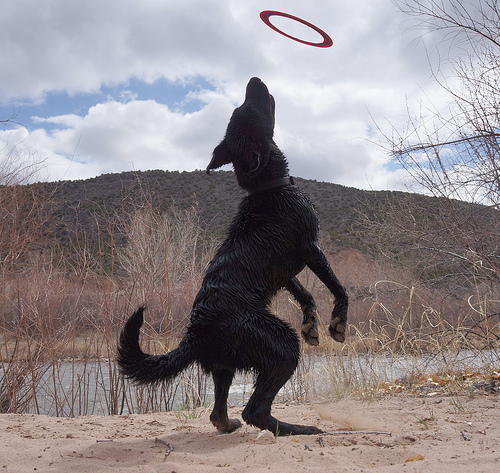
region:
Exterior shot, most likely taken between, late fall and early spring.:
[5, 1, 495, 462]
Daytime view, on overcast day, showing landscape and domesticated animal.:
[5, 5, 496, 470]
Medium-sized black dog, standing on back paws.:
[125, 60, 355, 450]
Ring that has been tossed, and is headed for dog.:
[256, 5, 329, 65]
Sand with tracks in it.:
[81, 417, 481, 469]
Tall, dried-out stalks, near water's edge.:
[12, 260, 497, 415]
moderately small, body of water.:
[28, 345, 493, 412]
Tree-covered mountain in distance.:
[15, 172, 493, 287]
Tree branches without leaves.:
[387, 7, 497, 232]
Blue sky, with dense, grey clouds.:
[13, 20, 485, 193]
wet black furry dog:
[110, 73, 350, 438]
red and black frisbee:
[256, 8, 337, 53]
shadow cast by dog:
[59, 428, 258, 465]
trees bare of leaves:
[1, 142, 207, 413]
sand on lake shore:
[7, 391, 493, 470]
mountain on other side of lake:
[3, 168, 498, 286]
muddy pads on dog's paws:
[298, 315, 345, 348]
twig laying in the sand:
[152, 433, 174, 462]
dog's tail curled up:
[115, 300, 198, 385]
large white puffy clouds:
[7, 4, 490, 194]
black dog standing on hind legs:
[175, 71, 340, 438]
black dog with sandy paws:
[291, 314, 353, 350]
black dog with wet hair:
[193, 130, 277, 375]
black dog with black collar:
[245, 167, 314, 199]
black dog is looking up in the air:
[211, 8, 333, 178]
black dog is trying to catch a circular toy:
[194, 3, 343, 243]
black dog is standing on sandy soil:
[69, 405, 414, 452]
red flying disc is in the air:
[243, 9, 350, 64]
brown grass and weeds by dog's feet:
[288, 326, 473, 400]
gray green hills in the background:
[21, 164, 490, 284]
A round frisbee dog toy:
[257, 8, 332, 49]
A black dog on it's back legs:
[116, 74, 349, 434]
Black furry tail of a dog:
[114, 306, 197, 381]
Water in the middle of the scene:
[0, 345, 497, 411]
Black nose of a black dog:
[244, 74, 262, 87]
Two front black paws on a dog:
[279, 243, 349, 345]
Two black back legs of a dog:
[197, 313, 320, 436]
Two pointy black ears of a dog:
[202, 139, 261, 174]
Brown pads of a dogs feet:
[300, 316, 345, 344]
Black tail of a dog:
[117, 308, 190, 382]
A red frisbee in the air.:
[237, 4, 355, 53]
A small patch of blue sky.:
[46, 70, 215, 133]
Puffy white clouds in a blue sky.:
[37, 85, 223, 166]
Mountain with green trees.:
[28, 173, 213, 245]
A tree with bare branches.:
[369, 8, 493, 222]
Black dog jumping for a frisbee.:
[101, 79, 366, 444]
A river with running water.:
[10, 356, 113, 418]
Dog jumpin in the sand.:
[310, 387, 485, 462]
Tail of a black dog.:
[65, 280, 202, 406]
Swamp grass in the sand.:
[310, 287, 482, 396]